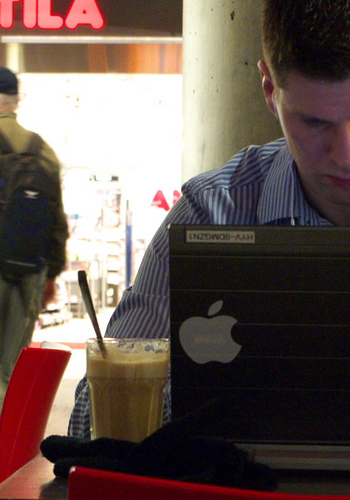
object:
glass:
[86, 337, 170, 443]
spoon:
[77, 269, 108, 360]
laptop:
[168, 223, 349, 479]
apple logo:
[177, 298, 242, 363]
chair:
[0, 340, 73, 486]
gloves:
[40, 422, 279, 492]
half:
[252, 59, 350, 209]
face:
[276, 74, 350, 208]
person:
[67, 0, 350, 439]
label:
[184, 230, 255, 245]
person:
[0, 65, 71, 418]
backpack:
[0, 126, 57, 284]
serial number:
[186, 230, 255, 244]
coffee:
[86, 349, 169, 443]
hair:
[257, 0, 349, 102]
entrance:
[18, 72, 182, 340]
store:
[19, 72, 183, 342]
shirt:
[67, 135, 337, 439]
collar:
[253, 142, 335, 229]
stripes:
[277, 165, 293, 207]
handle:
[77, 269, 108, 359]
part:
[77, 268, 93, 303]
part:
[171, 254, 216, 292]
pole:
[181, 0, 286, 196]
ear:
[256, 58, 278, 119]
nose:
[327, 120, 350, 170]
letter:
[63, 0, 106, 31]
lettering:
[24, 188, 38, 200]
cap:
[0, 65, 19, 95]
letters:
[0, 0, 38, 30]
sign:
[0, 0, 183, 38]